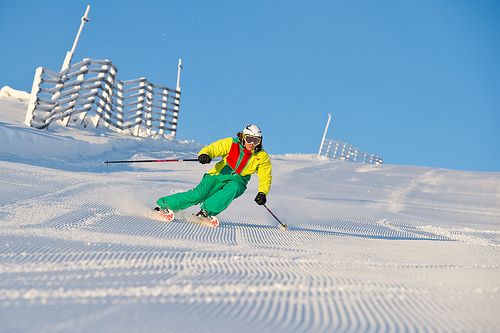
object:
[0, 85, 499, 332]
snow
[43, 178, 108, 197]
lines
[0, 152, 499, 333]
slope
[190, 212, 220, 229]
sking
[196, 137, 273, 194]
jacket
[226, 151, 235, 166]
red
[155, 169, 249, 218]
pants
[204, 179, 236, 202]
green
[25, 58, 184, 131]
fence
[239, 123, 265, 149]
helmet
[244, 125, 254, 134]
black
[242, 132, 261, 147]
goggles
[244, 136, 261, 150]
face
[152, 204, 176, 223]
skis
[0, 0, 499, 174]
bright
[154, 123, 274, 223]
skier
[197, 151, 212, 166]
gloves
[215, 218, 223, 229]
white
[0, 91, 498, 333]
mountain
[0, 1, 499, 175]
cloudless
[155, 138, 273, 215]
outfit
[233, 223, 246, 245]
tracks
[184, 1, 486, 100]
blue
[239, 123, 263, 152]
head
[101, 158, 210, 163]
pole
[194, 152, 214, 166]
hand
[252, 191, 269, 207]
glove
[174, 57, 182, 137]
wood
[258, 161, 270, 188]
yellow